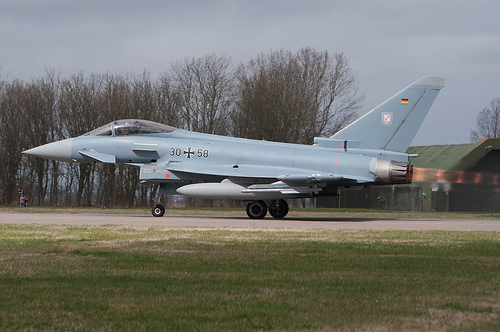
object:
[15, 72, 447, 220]
jet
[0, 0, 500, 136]
sky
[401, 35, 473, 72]
white clouds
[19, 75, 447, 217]
suv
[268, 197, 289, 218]
tire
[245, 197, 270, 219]
tire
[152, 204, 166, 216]
tire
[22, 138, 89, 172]
nose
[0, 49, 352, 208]
branches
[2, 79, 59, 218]
tree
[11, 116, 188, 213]
window plane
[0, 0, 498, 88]
clouds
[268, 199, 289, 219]
wheel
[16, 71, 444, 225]
plane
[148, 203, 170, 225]
wheel plane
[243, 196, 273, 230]
wheel plane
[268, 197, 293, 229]
wheel plane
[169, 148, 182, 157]
number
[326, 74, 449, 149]
tail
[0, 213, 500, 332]
grass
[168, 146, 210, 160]
sign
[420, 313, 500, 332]
spot